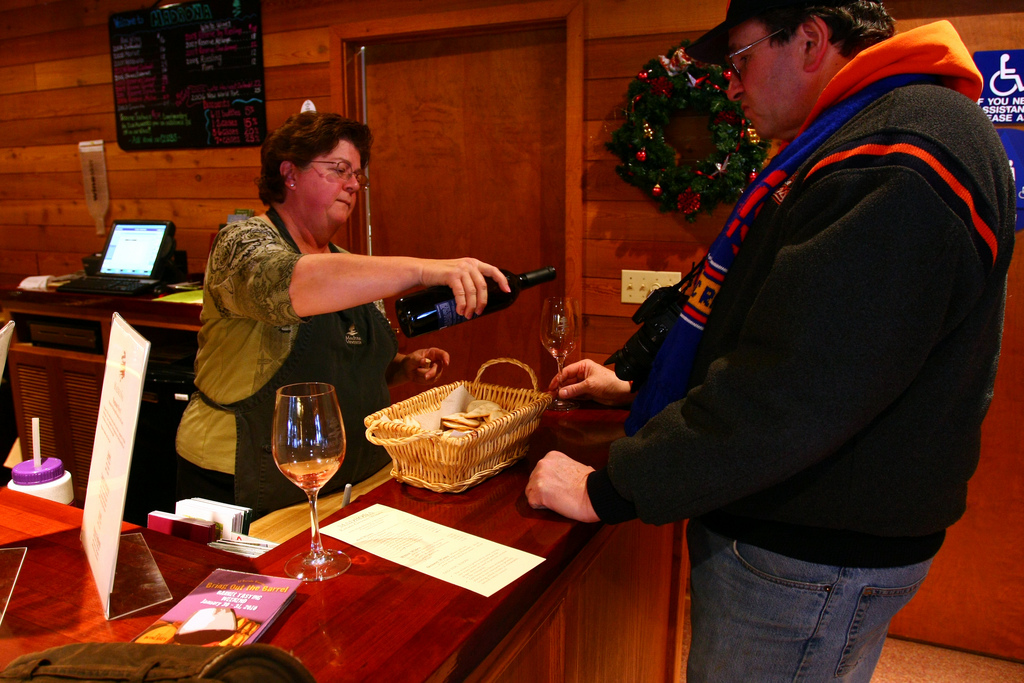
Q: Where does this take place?
A: At a restaurant.